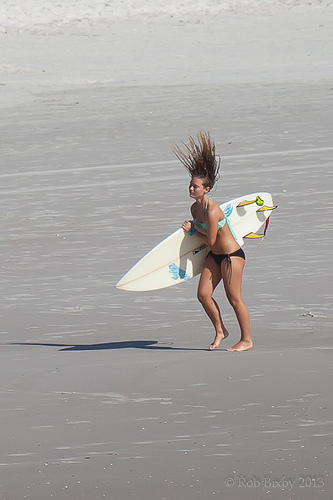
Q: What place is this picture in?
A: It is at the beach.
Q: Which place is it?
A: It is a beach.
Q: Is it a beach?
A: Yes, it is a beach.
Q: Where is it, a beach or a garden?
A: It is a beach.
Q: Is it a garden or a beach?
A: It is a beach.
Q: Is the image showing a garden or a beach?
A: It is showing a beach.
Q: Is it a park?
A: No, it is a beach.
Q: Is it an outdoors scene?
A: Yes, it is outdoors.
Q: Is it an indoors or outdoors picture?
A: It is outdoors.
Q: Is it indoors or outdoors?
A: It is outdoors.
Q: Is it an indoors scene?
A: No, it is outdoors.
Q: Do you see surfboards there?
A: Yes, there is a surfboard.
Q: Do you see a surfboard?
A: Yes, there is a surfboard.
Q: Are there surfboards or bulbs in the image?
A: Yes, there is a surfboard.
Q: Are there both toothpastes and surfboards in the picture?
A: No, there is a surfboard but no toothpastes.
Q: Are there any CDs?
A: No, there are no cds.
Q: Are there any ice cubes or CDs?
A: No, there are no CDs or ice cubes.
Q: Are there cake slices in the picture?
A: No, there are no cake slices.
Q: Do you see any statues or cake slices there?
A: No, there are no cake slices or statues.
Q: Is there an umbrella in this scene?
A: No, there are no umbrellas.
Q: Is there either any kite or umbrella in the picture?
A: No, there are no umbrellas or kites.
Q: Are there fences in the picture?
A: No, there are no fences.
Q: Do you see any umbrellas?
A: No, there are no umbrellas.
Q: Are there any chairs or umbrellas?
A: No, there are no umbrellas or chairs.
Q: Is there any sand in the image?
A: Yes, there is sand.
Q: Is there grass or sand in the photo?
A: Yes, there is sand.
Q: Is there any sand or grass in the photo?
A: Yes, there is sand.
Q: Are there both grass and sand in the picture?
A: No, there is sand but no grass.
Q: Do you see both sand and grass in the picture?
A: No, there is sand but no grass.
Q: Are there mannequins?
A: No, there are no mannequins.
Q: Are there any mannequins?
A: No, there are no mannequins.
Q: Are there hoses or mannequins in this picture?
A: No, there are no mannequins or hoses.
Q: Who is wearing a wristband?
A: The girl is wearing a wristband.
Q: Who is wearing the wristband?
A: The girl is wearing a wristband.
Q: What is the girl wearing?
A: The girl is wearing a wrist band.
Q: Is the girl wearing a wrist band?
A: Yes, the girl is wearing a wrist band.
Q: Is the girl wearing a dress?
A: No, the girl is wearing a wrist band.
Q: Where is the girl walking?
A: The girl is walking on the beach.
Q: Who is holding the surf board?
A: The girl is holding the surf board.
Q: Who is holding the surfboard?
A: The girl is holding the surf board.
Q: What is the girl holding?
A: The girl is holding the surfboard.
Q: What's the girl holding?
A: The girl is holding the surfboard.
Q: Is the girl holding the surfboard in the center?
A: Yes, the girl is holding the surf board.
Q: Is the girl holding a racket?
A: No, the girl is holding the surf board.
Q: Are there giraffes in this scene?
A: No, there are no giraffes.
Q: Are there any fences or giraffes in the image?
A: No, there are no giraffes or fences.